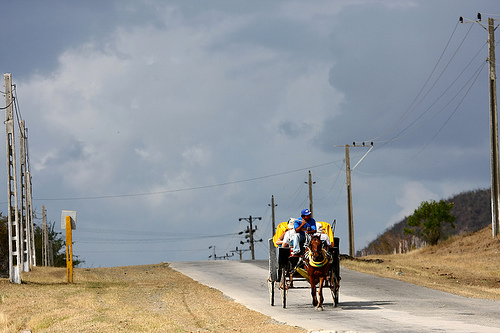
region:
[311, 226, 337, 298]
brown horse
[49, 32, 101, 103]
white clouds in blue sky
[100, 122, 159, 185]
white clouds in blue sky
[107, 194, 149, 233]
white clouds in blue sky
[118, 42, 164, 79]
white clouds in blue sky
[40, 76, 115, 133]
white clouds in blue sky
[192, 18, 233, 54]
white clouds in blue sky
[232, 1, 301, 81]
white clouds in blue sky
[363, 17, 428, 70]
white clouds in blue sky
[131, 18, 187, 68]
white clouds in blue sky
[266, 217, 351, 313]
brown horse pulling wagon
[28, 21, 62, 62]
white clouds in blue sky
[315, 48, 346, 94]
white clouds in blue sky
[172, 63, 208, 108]
white clouds in blue sky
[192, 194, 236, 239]
white clouds in blue sky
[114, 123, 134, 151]
white clouds in blue sky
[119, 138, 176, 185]
white clouds in blue sky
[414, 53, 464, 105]
white clouds in blue sky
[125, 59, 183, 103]
white clouds in blue sky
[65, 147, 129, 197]
white clouds in blue sky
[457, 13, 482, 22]
two birds sitting on the power lines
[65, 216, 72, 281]
yellow sign post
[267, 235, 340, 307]
horse and buggy on the road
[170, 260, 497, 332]
gray road on the hillside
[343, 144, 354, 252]
wooden post for electrical line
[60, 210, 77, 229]
metal street sign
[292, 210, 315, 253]
man is wearing a blue hat and shirt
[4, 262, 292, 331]
brown grass on the road side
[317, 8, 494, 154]
gray cloud in the sky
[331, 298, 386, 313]
horse shadow on the ground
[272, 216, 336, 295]
brown horse with wagon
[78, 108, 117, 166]
white clouds in blue sky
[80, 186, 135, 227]
white clouds in blue sky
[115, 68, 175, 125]
white clouds in blue sky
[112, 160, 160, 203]
white clouds in blue sky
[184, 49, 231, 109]
white clouds in blue sky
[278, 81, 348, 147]
white clouds in blue sky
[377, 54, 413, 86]
white clouds in blue sky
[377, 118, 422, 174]
white clouds in blue sky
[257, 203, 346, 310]
horse pulling a cart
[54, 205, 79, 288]
sign on a post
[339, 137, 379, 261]
telephone pole on the road side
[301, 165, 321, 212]
telephone pole on the road side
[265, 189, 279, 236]
telephone pole on the road side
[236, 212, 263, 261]
telephone pole on the road side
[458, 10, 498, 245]
telephone pole on the road side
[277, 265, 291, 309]
wheel on a cart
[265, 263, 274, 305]
wheel on a cart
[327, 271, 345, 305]
wheel on a cart